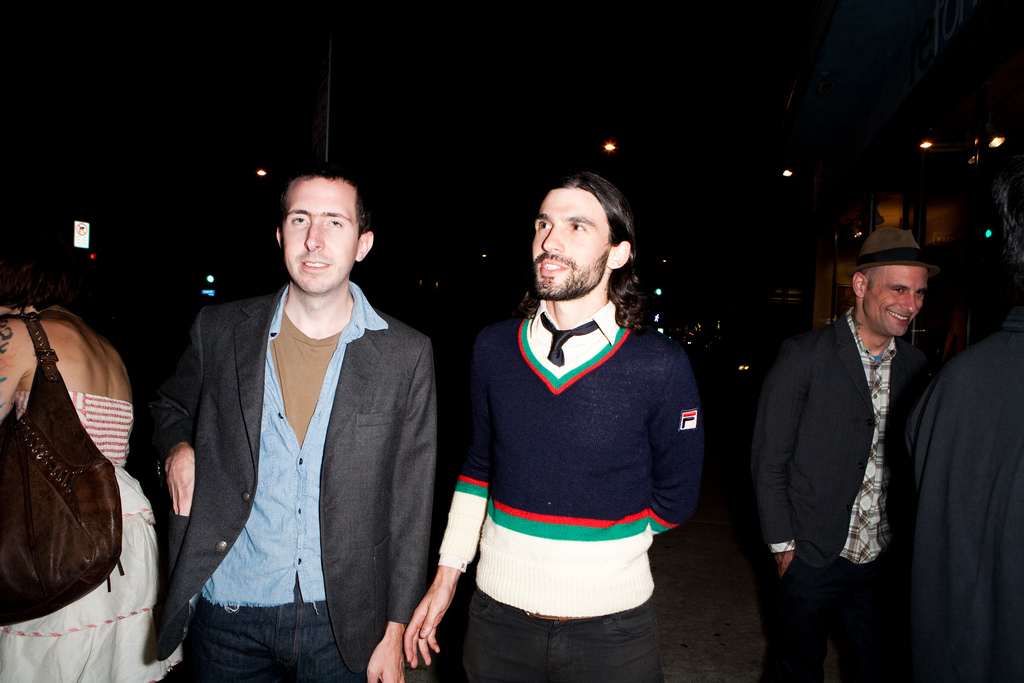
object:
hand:
[402, 576, 454, 667]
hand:
[363, 629, 403, 681]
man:
[397, 169, 712, 680]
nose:
[899, 293, 919, 314]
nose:
[542, 224, 565, 255]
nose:
[306, 220, 326, 252]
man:
[744, 226, 931, 683]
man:
[147, 163, 446, 683]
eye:
[571, 223, 586, 233]